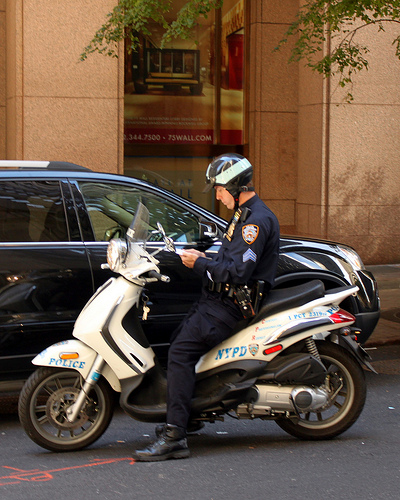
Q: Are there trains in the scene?
A: No, there are no trains.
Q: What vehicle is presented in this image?
A: The vehicle is a car.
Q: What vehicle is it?
A: The vehicle is a car.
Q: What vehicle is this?
A: This is a car.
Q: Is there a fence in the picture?
A: No, there are no fences.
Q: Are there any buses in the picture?
A: No, there are no buses.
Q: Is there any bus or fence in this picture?
A: No, there are no buses or fences.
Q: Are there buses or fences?
A: No, there are no buses or fences.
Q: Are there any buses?
A: No, there are no buses.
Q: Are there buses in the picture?
A: No, there are no buses.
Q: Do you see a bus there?
A: No, there are no buses.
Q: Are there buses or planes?
A: No, there are no buses or planes.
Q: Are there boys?
A: No, there are no boys.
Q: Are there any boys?
A: No, there are no boys.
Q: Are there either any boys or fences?
A: No, there are no boys or fences.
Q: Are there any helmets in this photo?
A: Yes, there is a helmet.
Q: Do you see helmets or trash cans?
A: Yes, there is a helmet.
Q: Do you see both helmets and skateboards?
A: No, there is a helmet but no skateboards.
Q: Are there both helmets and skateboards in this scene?
A: No, there is a helmet but no skateboards.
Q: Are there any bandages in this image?
A: No, there are no bandages.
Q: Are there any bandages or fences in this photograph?
A: No, there are no bandages or fences.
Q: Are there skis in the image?
A: No, there are no skis.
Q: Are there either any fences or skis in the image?
A: No, there are no skis or fences.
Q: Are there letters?
A: Yes, there are letters.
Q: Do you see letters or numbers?
A: Yes, there are letters.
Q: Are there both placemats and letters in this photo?
A: No, there are letters but no placemats.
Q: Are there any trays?
A: No, there are no trays.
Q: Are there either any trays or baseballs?
A: No, there are no trays or baseballs.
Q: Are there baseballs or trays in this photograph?
A: No, there are no trays or baseballs.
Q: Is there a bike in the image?
A: Yes, there is a bike.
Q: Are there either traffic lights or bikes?
A: Yes, there is a bike.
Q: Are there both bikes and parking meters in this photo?
A: No, there is a bike but no parking meters.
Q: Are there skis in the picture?
A: No, there are no skis.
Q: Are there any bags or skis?
A: No, there are no skis or bags.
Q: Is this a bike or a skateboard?
A: This is a bike.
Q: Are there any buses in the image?
A: No, there are no buses.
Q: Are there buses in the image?
A: No, there are no buses.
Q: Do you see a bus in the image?
A: No, there are no buses.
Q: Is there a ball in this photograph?
A: No, there are no balls.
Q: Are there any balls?
A: No, there are no balls.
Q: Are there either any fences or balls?
A: No, there are no balls or fences.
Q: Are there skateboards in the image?
A: No, there are no skateboards.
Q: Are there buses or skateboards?
A: No, there are no skateboards or buses.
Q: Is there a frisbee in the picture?
A: No, there are no frisbees.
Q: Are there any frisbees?
A: No, there are no frisbees.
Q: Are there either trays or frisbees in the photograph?
A: No, there are no frisbees or trays.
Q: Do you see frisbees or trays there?
A: No, there are no frisbees or trays.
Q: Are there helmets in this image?
A: Yes, there is a helmet.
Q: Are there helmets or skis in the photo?
A: Yes, there is a helmet.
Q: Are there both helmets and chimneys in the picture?
A: No, there is a helmet but no chimneys.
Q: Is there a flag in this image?
A: No, there are no flags.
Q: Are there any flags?
A: No, there are no flags.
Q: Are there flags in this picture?
A: No, there are no flags.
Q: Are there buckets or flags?
A: No, there are no flags or buckets.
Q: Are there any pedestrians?
A: No, there are no pedestrians.